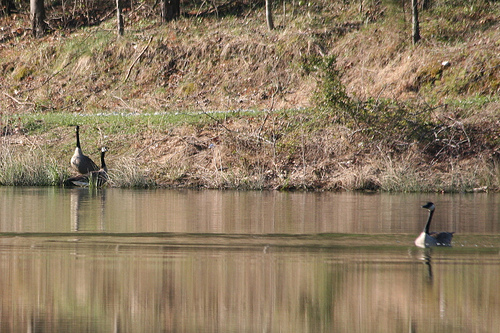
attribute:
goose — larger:
[68, 122, 101, 172]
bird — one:
[401, 194, 461, 254]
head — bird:
[422, 194, 433, 228]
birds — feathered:
[63, 120, 109, 188]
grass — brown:
[155, 130, 296, 176]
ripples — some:
[130, 230, 274, 259]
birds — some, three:
[58, 126, 456, 256]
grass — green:
[90, 110, 218, 125]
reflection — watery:
[230, 249, 360, 324]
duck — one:
[418, 196, 458, 254]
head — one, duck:
[418, 196, 433, 224]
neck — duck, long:
[60, 134, 92, 154]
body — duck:
[68, 145, 103, 174]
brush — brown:
[144, 144, 277, 187]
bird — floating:
[403, 194, 457, 251]